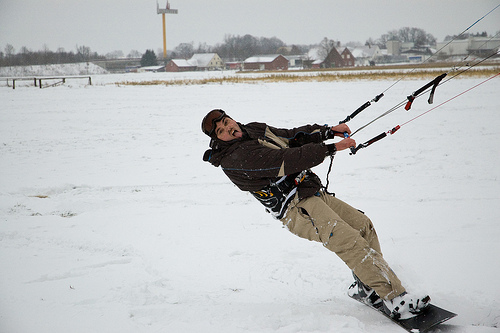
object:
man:
[197, 108, 431, 320]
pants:
[276, 191, 408, 301]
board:
[347, 279, 457, 332]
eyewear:
[200, 109, 226, 135]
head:
[201, 109, 245, 143]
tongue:
[233, 132, 242, 137]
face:
[209, 115, 243, 141]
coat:
[202, 122, 333, 219]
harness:
[288, 121, 395, 175]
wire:
[352, 74, 498, 153]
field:
[2, 74, 497, 332]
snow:
[0, 75, 499, 333]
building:
[243, 54, 287, 71]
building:
[303, 46, 356, 69]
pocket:
[296, 206, 312, 220]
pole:
[161, 12, 168, 61]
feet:
[381, 294, 432, 321]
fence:
[0, 76, 95, 89]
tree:
[140, 48, 158, 68]